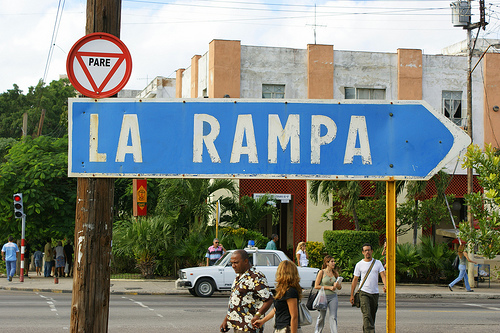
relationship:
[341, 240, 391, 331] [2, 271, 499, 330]
person crossing street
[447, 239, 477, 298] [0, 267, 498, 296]
woman walking along sidewalk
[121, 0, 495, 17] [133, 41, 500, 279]
powerline over building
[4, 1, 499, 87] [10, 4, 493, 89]
sky has cloud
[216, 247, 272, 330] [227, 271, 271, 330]
man wearing shirt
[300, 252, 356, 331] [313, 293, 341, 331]
woman wearing jeans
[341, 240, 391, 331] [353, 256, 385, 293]
person wearing shirt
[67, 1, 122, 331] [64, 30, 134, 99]
pole has sign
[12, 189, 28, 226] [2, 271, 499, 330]
stoplight across street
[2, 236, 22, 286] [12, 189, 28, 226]
man walking past stoplight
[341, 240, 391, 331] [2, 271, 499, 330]
person on street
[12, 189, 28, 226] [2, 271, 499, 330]
stoplight at street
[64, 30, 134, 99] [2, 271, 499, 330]
sign on street